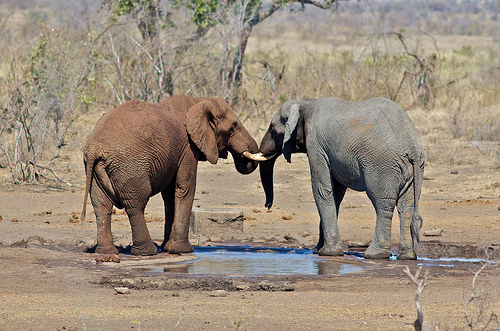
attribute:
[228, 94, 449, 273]
elephant — brown, gray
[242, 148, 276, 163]
tusk — long, white